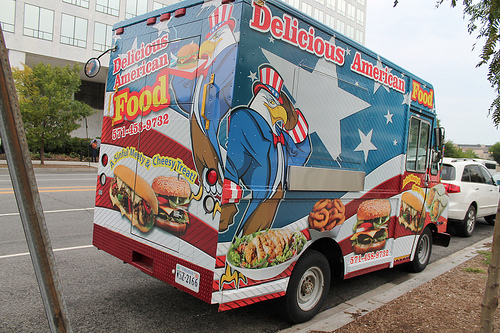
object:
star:
[352, 128, 378, 165]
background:
[0, 0, 82, 192]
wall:
[28, 109, 103, 148]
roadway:
[0, 169, 497, 331]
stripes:
[0, 188, 95, 195]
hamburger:
[355, 193, 390, 253]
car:
[435, 156, 497, 239]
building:
[0, 0, 366, 159]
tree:
[10, 57, 87, 186]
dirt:
[429, 311, 495, 330]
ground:
[323, 247, 496, 331]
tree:
[390, 2, 499, 332]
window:
[403, 113, 432, 173]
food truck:
[91, 1, 449, 321]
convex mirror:
[83, 45, 113, 78]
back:
[93, 5, 233, 302]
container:
[308, 226, 342, 237]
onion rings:
[311, 208, 329, 229]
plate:
[173, 263, 200, 294]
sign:
[247, 1, 405, 95]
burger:
[150, 174, 192, 234]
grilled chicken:
[241, 227, 300, 265]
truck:
[81, 0, 457, 323]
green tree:
[11, 62, 98, 165]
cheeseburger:
[349, 199, 391, 254]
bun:
[356, 200, 390, 221]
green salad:
[222, 230, 308, 270]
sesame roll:
[149, 175, 191, 198]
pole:
[1, 32, 75, 331]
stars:
[258, 34, 371, 162]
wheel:
[270, 245, 333, 326]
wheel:
[407, 228, 432, 274]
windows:
[38, 7, 53, 42]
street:
[2, 174, 488, 331]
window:
[285, 59, 379, 205]